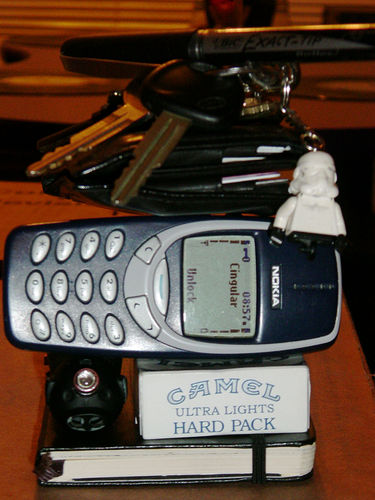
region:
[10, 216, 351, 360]
the cell phone is black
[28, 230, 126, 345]
the numbers are on phone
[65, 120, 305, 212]
the wallet is black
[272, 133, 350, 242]
the keychain is white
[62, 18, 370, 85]
the sharpie is black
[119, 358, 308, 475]
the cigarettes on book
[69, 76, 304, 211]
keys on top of wallet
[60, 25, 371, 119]
sharpie is on keys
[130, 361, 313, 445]
the cigarette pack is white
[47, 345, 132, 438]
the camera is black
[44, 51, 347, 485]
A pile of personal items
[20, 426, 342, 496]
A notebook on a desk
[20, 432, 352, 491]
A notebook on a wood desk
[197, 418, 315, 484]
A strap on a black notebook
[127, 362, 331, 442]
A pack of cigarettes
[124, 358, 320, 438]
A pack of Camel cigarettes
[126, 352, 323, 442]
A hard pack of Camel cigarettes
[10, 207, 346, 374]
A cell phone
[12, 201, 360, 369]
A Nokia cell phone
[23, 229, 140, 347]
The buttons on a cell phone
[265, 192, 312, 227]
part of a holder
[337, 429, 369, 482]
part of a table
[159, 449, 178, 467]
part of some pages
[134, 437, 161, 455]
edge of a book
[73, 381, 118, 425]
part of a toy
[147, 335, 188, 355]
edge of a phone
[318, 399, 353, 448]
part of a table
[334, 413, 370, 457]
part of a table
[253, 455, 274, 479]
part of a rope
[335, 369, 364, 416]
part of a table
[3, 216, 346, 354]
sideways Nokia cellular phone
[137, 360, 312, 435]
pack of Camel ultra light cigarettes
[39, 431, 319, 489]
white pages in a black bound book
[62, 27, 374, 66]
black sharpie permanent marker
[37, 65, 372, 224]
black keys sitting on a black wallet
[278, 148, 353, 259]
white storm trooper keychain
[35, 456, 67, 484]
dark bookmark stuck in one of the white pages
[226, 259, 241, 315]
text on phone screen designating the phone a Cingular phone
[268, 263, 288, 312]
black Nokia logo with white lettering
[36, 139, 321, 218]
black leather wallet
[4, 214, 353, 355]
a phone on the table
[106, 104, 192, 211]
one of the keys on the bunch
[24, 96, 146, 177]
one of the keys on the bunch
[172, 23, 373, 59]
a pen on top of the keys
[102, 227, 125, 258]
1 button on the phone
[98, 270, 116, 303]
two button on the phone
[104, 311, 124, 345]
three button on the phone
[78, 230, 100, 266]
four button on the phone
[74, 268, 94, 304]
five button on the phone